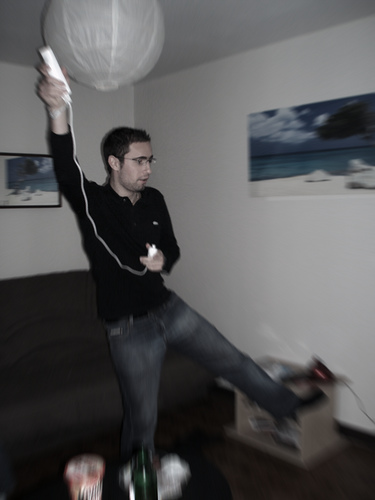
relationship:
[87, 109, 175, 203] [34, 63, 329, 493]
head of man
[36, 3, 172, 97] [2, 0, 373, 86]
lantern on ceiling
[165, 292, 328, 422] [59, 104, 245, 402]
leg below torso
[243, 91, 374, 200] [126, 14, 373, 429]
picture of beach on wall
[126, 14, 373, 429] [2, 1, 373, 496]
wall in room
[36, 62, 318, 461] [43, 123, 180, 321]
guy wearing shirt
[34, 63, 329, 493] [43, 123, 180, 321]
man wearing shirt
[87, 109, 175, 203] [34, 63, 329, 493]
head on man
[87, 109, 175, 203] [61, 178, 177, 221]
head above shoulders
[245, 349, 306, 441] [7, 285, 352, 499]
table on floor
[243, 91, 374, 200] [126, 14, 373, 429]
picture on wall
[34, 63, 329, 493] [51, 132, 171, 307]
man in shirt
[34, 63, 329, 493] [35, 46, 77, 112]
man holding wiimote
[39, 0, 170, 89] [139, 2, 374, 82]
round lamp hanging from ceiling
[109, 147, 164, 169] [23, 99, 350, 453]
small glasses on man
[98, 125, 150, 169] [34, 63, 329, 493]
hair on man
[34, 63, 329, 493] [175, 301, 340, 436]
man has left leg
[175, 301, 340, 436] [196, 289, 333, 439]
left leg in air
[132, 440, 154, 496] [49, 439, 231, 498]
bottle on table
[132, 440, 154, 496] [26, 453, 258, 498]
bottle on table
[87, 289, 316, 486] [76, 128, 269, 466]
jeans on man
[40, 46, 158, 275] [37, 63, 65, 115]
remote controller in hand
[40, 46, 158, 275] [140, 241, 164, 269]
remote controller in hand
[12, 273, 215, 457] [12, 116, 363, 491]
gray sofa in room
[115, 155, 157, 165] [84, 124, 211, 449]
eyeglasses on man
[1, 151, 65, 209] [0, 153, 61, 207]
picture has frame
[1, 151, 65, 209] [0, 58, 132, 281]
picture on wall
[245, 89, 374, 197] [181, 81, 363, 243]
poster on wall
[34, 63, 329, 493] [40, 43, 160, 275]
man playing game